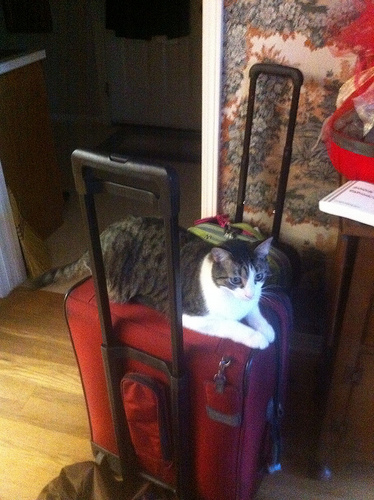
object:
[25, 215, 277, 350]
cat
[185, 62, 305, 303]
suitcase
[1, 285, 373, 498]
floor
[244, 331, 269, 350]
paw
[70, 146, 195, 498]
handle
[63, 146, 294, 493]
suitcase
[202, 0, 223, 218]
door frame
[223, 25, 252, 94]
flower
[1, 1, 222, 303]
door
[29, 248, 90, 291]
tail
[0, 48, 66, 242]
cabinet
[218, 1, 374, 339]
wallpaper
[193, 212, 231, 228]
tag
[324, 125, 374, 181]
bowl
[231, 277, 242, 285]
eye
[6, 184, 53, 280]
broom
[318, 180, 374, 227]
book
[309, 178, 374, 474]
table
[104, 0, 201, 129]
door